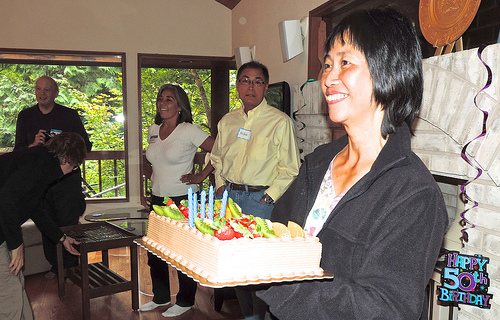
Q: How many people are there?
A: Four.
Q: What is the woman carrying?
A: A cake.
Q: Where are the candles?
A: On the cake.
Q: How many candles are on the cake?
A: Five.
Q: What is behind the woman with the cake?
A: A birthday present.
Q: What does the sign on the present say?
A: Happy 50th Birthday.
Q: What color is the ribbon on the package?
A: Purple.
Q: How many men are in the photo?
A: Two.